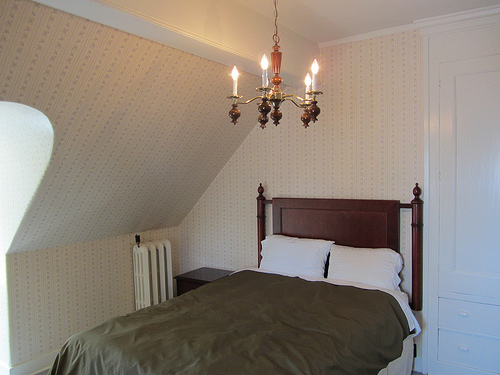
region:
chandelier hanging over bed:
[208, 8, 348, 130]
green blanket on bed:
[47, 260, 412, 374]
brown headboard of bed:
[242, 174, 432, 301]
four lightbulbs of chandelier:
[227, 50, 321, 92]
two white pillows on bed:
[251, 226, 408, 297]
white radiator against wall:
[127, 227, 179, 307]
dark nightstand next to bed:
[169, 253, 231, 294]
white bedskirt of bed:
[383, 341, 426, 371]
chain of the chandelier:
[262, 5, 291, 50]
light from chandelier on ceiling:
[181, 5, 316, 100]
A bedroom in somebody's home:
[7, 26, 482, 367]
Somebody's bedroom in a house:
[36, 28, 492, 355]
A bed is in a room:
[21, 25, 476, 367]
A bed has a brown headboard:
[21, 97, 487, 372]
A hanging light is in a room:
[10, 25, 486, 367]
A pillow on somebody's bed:
[330, 245, 397, 280]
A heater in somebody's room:
[130, 245, 170, 295]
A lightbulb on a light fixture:
[257, 52, 268, 72]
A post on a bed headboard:
[410, 196, 423, 306]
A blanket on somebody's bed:
[228, 286, 328, 353]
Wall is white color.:
[76, 80, 190, 217]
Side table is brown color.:
[171, 256, 218, 299]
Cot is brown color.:
[238, 180, 426, 284]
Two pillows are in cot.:
[252, 230, 417, 311]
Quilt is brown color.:
[148, 306, 282, 351]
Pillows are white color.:
[256, 230, 364, 290]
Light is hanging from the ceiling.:
[200, 15, 337, 167]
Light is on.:
[195, 18, 352, 154]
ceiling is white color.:
[181, 7, 411, 34]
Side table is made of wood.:
[163, 254, 237, 298]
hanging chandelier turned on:
[229, 1, 321, 128]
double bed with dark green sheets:
[46, 183, 423, 374]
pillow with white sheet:
[326, 245, 401, 289]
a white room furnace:
[132, 233, 174, 309]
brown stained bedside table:
[175, 265, 232, 297]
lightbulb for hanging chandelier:
[310, 55, 320, 75]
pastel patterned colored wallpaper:
[0, 0, 135, 313]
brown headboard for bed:
[255, 183, 423, 306]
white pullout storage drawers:
[427, 294, 499, 374]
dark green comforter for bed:
[50, 278, 410, 373]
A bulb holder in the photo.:
[269, 12, 284, 89]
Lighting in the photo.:
[300, 57, 319, 96]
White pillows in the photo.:
[327, 248, 403, 288]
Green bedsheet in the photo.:
[170, 288, 334, 363]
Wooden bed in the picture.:
[254, 183, 424, 299]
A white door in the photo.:
[427, 29, 496, 372]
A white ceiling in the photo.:
[309, 0, 384, 40]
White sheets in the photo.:
[405, 288, 420, 373]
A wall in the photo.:
[349, 66, 412, 161]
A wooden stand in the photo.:
[412, 180, 424, 309]